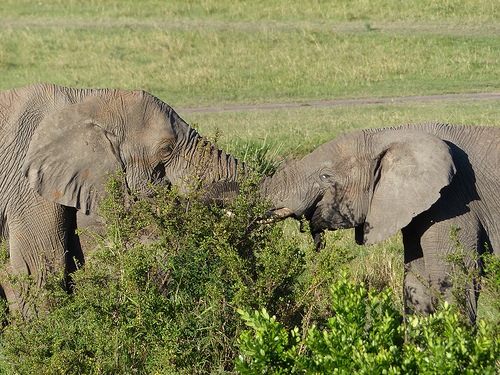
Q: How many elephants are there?
A: Two.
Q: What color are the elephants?
A: Grey.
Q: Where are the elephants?
A: In the field.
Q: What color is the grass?
A: Green.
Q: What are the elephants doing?
A: Locking trunks.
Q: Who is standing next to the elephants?
A: Noone.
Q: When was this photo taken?
A: In the daytime.